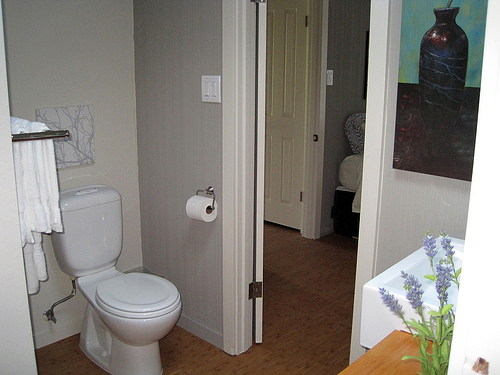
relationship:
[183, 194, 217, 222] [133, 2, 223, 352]
tissue on wall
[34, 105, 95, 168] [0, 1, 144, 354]
picture on wall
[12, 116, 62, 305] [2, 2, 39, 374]
towel hanging on wall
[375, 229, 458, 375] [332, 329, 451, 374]
flowers on table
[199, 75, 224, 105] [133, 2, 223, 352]
light switch on wall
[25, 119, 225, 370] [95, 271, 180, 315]
toilet has lid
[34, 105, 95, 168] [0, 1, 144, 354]
painting hanging on wall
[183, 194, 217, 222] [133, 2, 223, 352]
paper on a wall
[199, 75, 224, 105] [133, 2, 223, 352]
light switches on a wall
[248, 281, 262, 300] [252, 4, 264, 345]
hinge on a door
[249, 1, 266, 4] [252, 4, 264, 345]
hinge on a door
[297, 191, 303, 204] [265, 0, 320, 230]
hinge on a door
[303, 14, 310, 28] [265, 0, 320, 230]
hinge on a door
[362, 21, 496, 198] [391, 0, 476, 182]
wall has painting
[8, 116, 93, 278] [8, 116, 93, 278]
towels are on rack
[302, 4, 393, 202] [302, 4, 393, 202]
wall on bathroom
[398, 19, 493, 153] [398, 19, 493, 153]
artwork on wall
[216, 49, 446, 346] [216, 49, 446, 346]
doorway in bathroom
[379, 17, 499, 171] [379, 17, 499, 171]
painting on vase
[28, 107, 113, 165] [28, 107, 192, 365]
artwork hanging above stool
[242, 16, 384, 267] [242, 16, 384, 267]
door in room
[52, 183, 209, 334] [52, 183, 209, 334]
seat on toilet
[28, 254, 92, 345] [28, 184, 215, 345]
valve on toilet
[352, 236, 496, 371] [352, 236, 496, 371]
flowers on table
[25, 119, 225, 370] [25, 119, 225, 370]
toilet in bathroom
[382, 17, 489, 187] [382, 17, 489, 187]
picture on wall